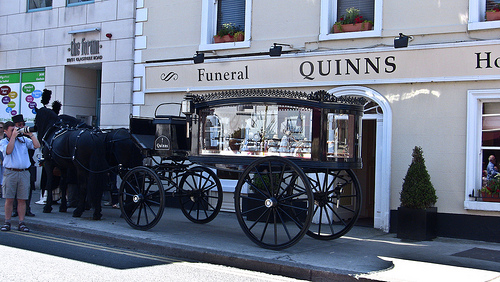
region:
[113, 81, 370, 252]
A horse drawn carriage is in front of a funeral home.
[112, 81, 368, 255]
The color of a horse-drawn carriage is black and white.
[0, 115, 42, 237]
A man is taking a picture.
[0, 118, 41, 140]
A man is holding a camera.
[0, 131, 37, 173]
A man is wearing a white shirt.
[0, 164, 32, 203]
A man is wearing tan pants.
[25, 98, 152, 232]
Two horses are attached to a carriage.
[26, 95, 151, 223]
The color of two horses is black.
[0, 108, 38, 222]
A man is standing behind another man.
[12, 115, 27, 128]
A man is wearing sunglasses.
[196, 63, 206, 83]
The letter is black.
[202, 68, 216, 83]
The letter is black.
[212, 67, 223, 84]
The letter is black.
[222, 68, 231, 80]
The letter is black.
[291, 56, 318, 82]
The letter is black.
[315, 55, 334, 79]
The letter is black.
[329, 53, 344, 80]
The letter is black.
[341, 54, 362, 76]
The letter is black.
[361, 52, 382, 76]
The letter is black.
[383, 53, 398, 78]
The letter is black.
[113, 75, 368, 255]
A wagon in the foreground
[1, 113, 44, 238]
Two people in the foreground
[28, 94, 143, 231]
A side view of two horses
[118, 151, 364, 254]
Wagon's wheels are black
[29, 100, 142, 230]
The horse's coat is black in color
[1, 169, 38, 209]
Man is wearing shorts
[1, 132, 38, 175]
Man is wearing a dress shirt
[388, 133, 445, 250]
A small tree in a black pot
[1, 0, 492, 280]
Photo was taken in the daytime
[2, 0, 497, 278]
Photo was taken outdoors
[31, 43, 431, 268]
Carriage on the road.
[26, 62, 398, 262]
Horses with a carriage.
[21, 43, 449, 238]
Horses pulling the carriage.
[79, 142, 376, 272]
Wheels on the carriage.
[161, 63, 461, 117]
Words on the building.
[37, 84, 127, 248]
Black horses with the carriage.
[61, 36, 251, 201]
Door on the building.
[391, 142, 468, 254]
Tree by the building.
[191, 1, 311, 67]
Window on the building.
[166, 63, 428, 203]
Clear carriage on wheels.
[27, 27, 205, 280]
a horse on the sidewalk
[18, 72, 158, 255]
a black horse on the sidewalk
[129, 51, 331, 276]
a carraige on a sidewalk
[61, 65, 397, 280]
a horse carriage on a sidewalk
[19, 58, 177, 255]
a horse wearing a hat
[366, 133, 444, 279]
a tree on a sidewalk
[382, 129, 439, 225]
a bus on the sidewalk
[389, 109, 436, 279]
a tree in a pot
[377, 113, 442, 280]
a bus on a pot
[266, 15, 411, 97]
business on a building